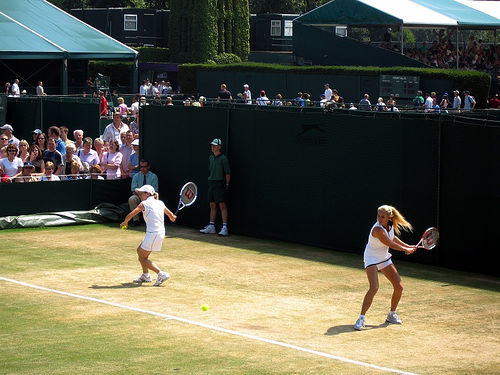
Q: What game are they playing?
A: Tennis.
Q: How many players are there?
A: Two.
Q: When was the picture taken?
A: Daytime.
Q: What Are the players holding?
A: Tennis racquets.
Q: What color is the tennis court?
A: Green.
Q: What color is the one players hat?
A: White.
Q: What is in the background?
A: People.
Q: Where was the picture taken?
A: At a tennis match.